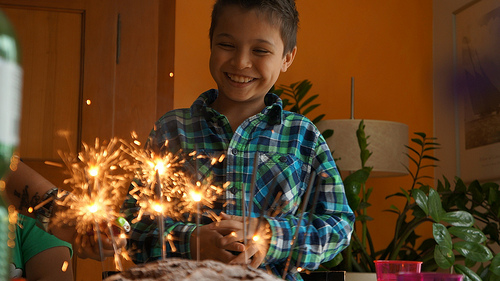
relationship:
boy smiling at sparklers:
[114, 1, 357, 280] [64, 131, 234, 278]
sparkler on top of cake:
[192, 171, 207, 267] [107, 255, 289, 279]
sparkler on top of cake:
[148, 159, 169, 262] [107, 255, 289, 279]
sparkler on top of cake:
[243, 150, 270, 268] [107, 255, 289, 279]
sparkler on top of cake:
[80, 190, 108, 279] [107, 255, 289, 279]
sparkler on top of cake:
[281, 167, 317, 280] [107, 255, 289, 279]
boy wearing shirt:
[114, 1, 357, 280] [119, 89, 357, 280]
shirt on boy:
[119, 89, 357, 280] [114, 1, 357, 280]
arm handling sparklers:
[1, 152, 121, 254] [64, 131, 234, 278]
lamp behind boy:
[303, 72, 410, 269] [114, 1, 357, 280]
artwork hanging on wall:
[431, 2, 499, 178] [174, 2, 499, 261]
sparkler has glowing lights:
[148, 159, 169, 262] [135, 141, 183, 193]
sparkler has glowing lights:
[192, 171, 207, 267] [172, 171, 219, 222]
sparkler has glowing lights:
[80, 190, 108, 279] [60, 129, 126, 195]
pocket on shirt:
[245, 150, 311, 215] [119, 89, 357, 280]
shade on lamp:
[314, 117, 410, 177] [303, 72, 410, 269]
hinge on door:
[112, 11, 125, 67] [2, 0, 125, 279]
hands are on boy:
[195, 209, 269, 271] [114, 1, 357, 280]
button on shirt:
[229, 146, 243, 156] [119, 89, 357, 280]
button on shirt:
[279, 154, 289, 163] [119, 89, 357, 280]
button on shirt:
[230, 185, 240, 194] [119, 89, 357, 280]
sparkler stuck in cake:
[148, 159, 169, 262] [107, 255, 289, 279]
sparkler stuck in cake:
[192, 171, 207, 267] [107, 255, 289, 279]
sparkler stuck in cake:
[80, 190, 108, 279] [107, 255, 289, 279]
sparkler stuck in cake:
[243, 150, 270, 268] [107, 255, 289, 279]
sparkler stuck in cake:
[281, 167, 317, 280] [107, 255, 289, 279]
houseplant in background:
[343, 176, 487, 280] [15, 4, 499, 252]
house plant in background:
[274, 79, 499, 281] [15, 4, 499, 252]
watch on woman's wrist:
[36, 182, 60, 234] [38, 176, 76, 239]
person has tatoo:
[0, 16, 133, 259] [9, 185, 51, 218]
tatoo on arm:
[9, 185, 51, 218] [1, 152, 121, 254]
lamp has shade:
[303, 72, 410, 269] [314, 117, 410, 177]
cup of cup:
[373, 259, 461, 281] [374, 257, 421, 278]